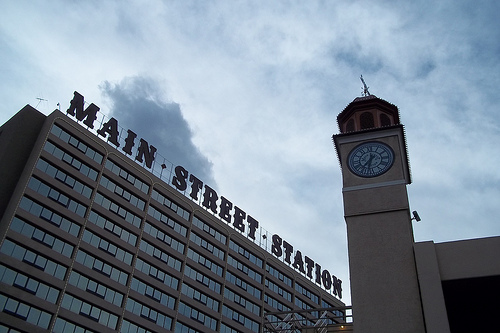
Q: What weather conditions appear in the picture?
A: It is cloudy.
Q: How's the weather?
A: It is cloudy.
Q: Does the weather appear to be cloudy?
A: Yes, it is cloudy.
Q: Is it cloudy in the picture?
A: Yes, it is cloudy.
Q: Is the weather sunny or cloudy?
A: It is cloudy.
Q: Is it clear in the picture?
A: No, it is cloudy.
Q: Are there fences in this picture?
A: No, there are no fences.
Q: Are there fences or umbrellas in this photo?
A: No, there are no fences or umbrellas.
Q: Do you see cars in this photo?
A: No, there are no cars.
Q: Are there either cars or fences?
A: No, there are no cars or fences.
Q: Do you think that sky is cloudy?
A: Yes, the sky is cloudy.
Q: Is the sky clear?
A: No, the sky is cloudy.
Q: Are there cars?
A: No, there are no cars.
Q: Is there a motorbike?
A: No, there are no motorcycles.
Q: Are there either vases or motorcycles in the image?
A: No, there are no motorcycles or vases.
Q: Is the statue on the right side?
A: Yes, the statue is on the right of the image.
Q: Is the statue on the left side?
A: No, the statue is on the right of the image.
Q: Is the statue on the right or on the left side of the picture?
A: The statue is on the right of the image.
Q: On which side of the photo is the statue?
A: The statue is on the right of the image.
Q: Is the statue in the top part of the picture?
A: Yes, the statue is in the top of the image.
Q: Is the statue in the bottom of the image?
A: No, the statue is in the top of the image.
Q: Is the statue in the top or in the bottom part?
A: The statue is in the top of the image.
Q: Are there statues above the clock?
A: Yes, there is a statue above the clock.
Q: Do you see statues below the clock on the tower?
A: No, the statue is above the clock.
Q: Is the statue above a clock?
A: Yes, the statue is above a clock.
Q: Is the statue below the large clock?
A: No, the statue is above the clock.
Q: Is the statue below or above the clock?
A: The statue is above the clock.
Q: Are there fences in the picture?
A: No, there are no fences.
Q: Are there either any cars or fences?
A: No, there are no fences or cars.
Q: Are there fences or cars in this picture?
A: No, there are no fences or cars.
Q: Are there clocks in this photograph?
A: Yes, there is a clock.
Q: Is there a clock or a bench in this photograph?
A: Yes, there is a clock.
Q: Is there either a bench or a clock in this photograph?
A: Yes, there is a clock.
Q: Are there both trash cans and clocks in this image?
A: No, there is a clock but no trash cans.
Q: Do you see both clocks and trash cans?
A: No, there is a clock but no trash cans.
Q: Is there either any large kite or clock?
A: Yes, there is a large clock.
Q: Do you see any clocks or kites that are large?
A: Yes, the clock is large.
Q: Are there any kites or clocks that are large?
A: Yes, the clock is large.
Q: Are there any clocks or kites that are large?
A: Yes, the clock is large.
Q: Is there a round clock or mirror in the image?
A: Yes, there is a round clock.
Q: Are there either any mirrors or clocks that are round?
A: Yes, the clock is round.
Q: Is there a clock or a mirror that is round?
A: Yes, the clock is round.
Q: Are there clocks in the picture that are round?
A: Yes, there is a round clock.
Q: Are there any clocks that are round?
A: Yes, there is a clock that is round.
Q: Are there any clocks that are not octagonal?
A: Yes, there is an round clock.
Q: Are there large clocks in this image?
A: Yes, there is a large clock.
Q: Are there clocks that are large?
A: Yes, there is a clock that is large.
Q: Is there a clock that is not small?
A: Yes, there is a large clock.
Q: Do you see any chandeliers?
A: No, there are no chandeliers.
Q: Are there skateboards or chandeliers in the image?
A: No, there are no chandeliers or skateboards.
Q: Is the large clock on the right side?
A: Yes, the clock is on the right of the image.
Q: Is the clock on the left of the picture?
A: No, the clock is on the right of the image.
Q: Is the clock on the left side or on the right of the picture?
A: The clock is on the right of the image.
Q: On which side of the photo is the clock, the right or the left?
A: The clock is on the right of the image.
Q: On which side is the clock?
A: The clock is on the right of the image.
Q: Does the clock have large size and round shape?
A: Yes, the clock is large and round.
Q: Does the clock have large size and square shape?
A: No, the clock is large but round.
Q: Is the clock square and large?
A: No, the clock is large but round.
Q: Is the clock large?
A: Yes, the clock is large.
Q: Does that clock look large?
A: Yes, the clock is large.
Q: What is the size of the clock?
A: The clock is large.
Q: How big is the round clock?
A: The clock is large.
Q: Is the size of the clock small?
A: No, the clock is large.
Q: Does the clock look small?
A: No, the clock is large.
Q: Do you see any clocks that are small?
A: No, there is a clock but it is large.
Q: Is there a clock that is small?
A: No, there is a clock but it is large.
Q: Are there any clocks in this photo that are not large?
A: No, there is a clock but it is large.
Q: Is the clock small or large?
A: The clock is large.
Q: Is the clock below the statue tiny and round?
A: No, the clock is round but large.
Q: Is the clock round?
A: Yes, the clock is round.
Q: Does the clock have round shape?
A: Yes, the clock is round.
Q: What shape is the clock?
A: The clock is round.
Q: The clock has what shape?
A: The clock is round.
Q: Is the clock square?
A: No, the clock is round.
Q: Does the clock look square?
A: No, the clock is round.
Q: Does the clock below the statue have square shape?
A: No, the clock is round.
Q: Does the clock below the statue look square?
A: No, the clock is round.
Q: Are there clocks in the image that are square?
A: No, there is a clock but it is round.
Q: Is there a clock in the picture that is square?
A: No, there is a clock but it is round.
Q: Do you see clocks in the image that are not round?
A: No, there is a clock but it is round.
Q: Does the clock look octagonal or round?
A: The clock is round.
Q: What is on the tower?
A: The clock is on the tower.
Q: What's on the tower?
A: The clock is on the tower.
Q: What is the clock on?
A: The clock is on the tower.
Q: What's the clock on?
A: The clock is on the tower.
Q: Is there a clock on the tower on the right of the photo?
A: Yes, there is a clock on the tower.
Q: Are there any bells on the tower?
A: No, there is a clock on the tower.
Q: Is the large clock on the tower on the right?
A: Yes, the clock is on the tower.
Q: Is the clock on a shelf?
A: No, the clock is on the tower.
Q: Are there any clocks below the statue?
A: Yes, there is a clock below the statue.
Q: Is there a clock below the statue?
A: Yes, there is a clock below the statue.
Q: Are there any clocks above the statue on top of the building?
A: No, the clock is below the statue.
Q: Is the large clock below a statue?
A: Yes, the clock is below a statue.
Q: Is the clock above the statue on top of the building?
A: No, the clock is below the statue.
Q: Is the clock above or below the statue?
A: The clock is below the statue.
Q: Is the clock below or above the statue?
A: The clock is below the statue.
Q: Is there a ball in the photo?
A: No, there are no balls.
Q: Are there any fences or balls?
A: No, there are no balls or fences.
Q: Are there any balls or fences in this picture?
A: No, there are no balls or fences.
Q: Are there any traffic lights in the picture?
A: No, there are no traffic lights.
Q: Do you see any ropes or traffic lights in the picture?
A: No, there are no traffic lights or ropes.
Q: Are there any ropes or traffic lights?
A: No, there are no traffic lights or ropes.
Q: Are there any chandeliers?
A: No, there are no chandeliers.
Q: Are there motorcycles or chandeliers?
A: No, there are no chandeliers or motorcycles.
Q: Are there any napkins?
A: No, there are no napkins.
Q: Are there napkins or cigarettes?
A: No, there are no napkins or cigarettes.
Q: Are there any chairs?
A: No, there are no chairs.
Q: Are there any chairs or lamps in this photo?
A: No, there are no chairs or lamps.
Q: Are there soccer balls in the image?
A: No, there are no soccer balls.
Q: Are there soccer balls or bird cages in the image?
A: No, there are no soccer balls or bird cages.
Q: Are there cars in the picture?
A: No, there are no cars.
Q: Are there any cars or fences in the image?
A: No, there are no cars or fences.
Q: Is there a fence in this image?
A: No, there are no fences.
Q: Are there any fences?
A: No, there are no fences.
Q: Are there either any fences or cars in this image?
A: No, there are no fences or cars.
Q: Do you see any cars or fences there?
A: No, there are no fences or cars.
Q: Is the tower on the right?
A: Yes, the tower is on the right of the image.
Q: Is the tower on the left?
A: No, the tower is on the right of the image.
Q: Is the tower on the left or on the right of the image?
A: The tower is on the right of the image.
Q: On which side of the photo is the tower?
A: The tower is on the right of the image.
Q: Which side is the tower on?
A: The tower is on the right of the image.